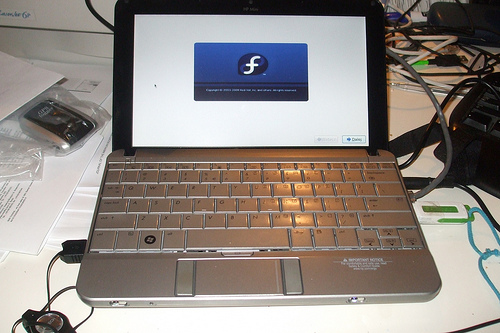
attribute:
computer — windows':
[75, 2, 441, 305]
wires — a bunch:
[380, 0, 498, 202]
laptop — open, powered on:
[75, 27, 445, 309]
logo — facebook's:
[183, 35, 318, 114]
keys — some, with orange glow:
[301, 163, 395, 253]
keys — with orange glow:
[100, 163, 244, 251]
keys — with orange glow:
[262, 170, 361, 183]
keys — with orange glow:
[89, 161, 428, 248]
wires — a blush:
[382, 2, 492, 114]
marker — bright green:
[411, 54, 429, 70]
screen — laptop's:
[86, 9, 395, 148]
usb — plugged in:
[411, 193, 472, 227]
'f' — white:
[237, 51, 269, 78]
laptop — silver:
[72, 1, 442, 302]